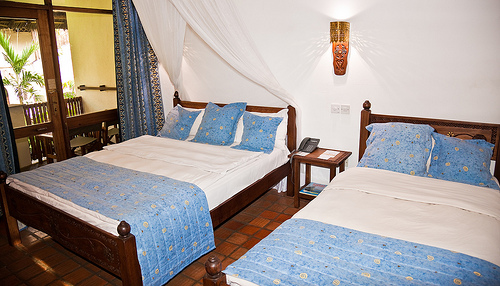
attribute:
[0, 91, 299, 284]
bed — wood, wooden, brown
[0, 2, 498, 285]
room — tropical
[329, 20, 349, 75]
light — tropical theme, on, decorative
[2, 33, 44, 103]
tree — small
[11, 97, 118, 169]
patio — outdoor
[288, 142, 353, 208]
nightstand — small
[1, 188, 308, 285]
floor — tile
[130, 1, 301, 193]
net — white, large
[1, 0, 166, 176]
curtains — tropical, blue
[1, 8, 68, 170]
door — wood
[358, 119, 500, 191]
pillows — blue, white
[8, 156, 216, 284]
bedspread — blue, yellow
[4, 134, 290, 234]
sheet — white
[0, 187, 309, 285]
tile — terracotta, brown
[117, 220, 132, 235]
knob — wooden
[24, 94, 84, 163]
railing — protection